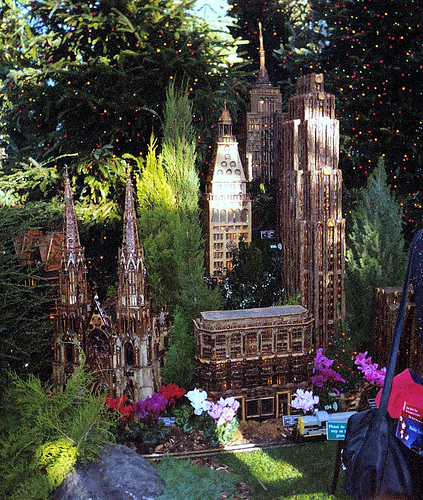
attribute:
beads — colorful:
[311, 4, 422, 250]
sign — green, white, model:
[323, 417, 353, 444]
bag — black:
[335, 395, 415, 483]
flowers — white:
[163, 378, 240, 437]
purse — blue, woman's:
[342, 230, 421, 498]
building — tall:
[277, 68, 371, 336]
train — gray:
[283, 412, 346, 444]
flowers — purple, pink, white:
[99, 369, 256, 447]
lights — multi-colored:
[335, 28, 414, 104]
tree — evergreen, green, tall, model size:
[334, 154, 410, 351]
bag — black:
[353, 402, 420, 496]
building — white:
[279, 71, 349, 346]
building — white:
[247, 16, 282, 262]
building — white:
[206, 97, 253, 275]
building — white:
[103, 166, 176, 405]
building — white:
[44, 162, 108, 389]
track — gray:
[140, 436, 299, 463]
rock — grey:
[62, 437, 164, 498]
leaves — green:
[174, 412, 216, 451]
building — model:
[199, 92, 256, 295]